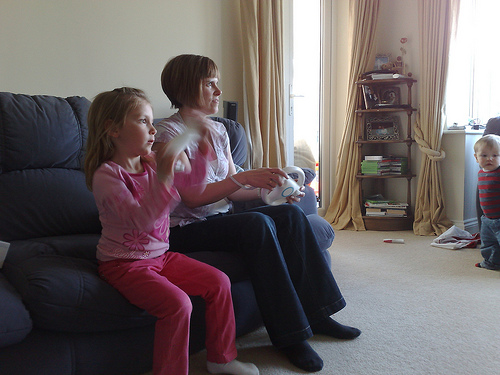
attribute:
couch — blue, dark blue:
[1, 90, 334, 354]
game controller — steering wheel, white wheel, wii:
[260, 166, 310, 206]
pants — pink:
[106, 252, 242, 375]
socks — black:
[285, 311, 362, 371]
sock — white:
[205, 360, 264, 374]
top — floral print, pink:
[88, 159, 204, 262]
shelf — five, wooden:
[353, 69, 422, 231]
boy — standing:
[469, 132, 499, 274]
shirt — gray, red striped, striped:
[475, 167, 499, 217]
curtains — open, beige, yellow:
[414, 0, 453, 235]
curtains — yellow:
[330, 2, 376, 229]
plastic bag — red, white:
[429, 224, 482, 256]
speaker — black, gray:
[223, 97, 241, 120]